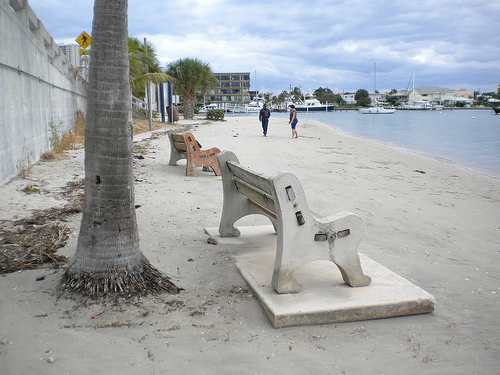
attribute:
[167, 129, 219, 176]
bench — brown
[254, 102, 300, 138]
people walking — on sand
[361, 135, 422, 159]
water — at the edge of sand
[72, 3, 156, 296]
palm tree — in the sand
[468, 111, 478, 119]
white buoy — in the water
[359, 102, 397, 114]
white boat — in the water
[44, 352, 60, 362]
rock — on the sand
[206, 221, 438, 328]
white base — of bench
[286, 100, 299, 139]
woman — wearing blue clothing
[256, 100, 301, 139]
people — walking by the seaside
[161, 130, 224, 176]
bench — with wooden slats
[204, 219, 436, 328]
concrete slab — supporting bench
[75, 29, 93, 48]
street sign — yellow and black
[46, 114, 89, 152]
dry/brown weeds — growing along wall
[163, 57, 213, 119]
palm trees — standing in the sand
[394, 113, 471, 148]
sea water — calm blue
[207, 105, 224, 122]
green bush — small, growing in sand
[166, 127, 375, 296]
benches — facing the water, in front the ocean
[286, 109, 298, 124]
suit — blue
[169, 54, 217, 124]
tree — green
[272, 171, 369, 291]
bench side — cement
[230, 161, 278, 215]
planks — wooden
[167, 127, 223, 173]
bench — wooden